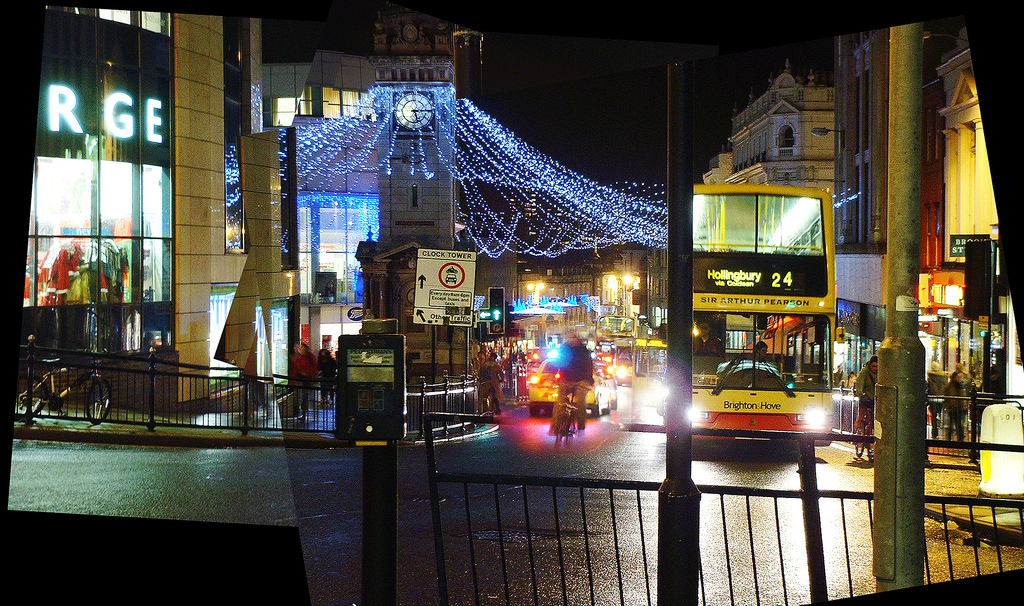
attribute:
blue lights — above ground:
[226, 80, 669, 264]